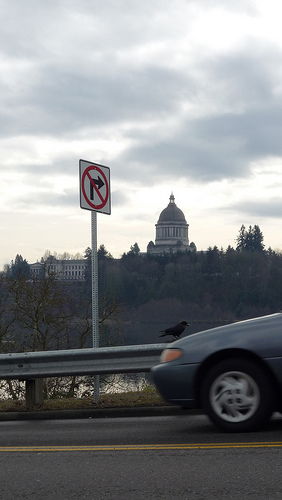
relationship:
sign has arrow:
[76, 158, 115, 218] [94, 175, 106, 186]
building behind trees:
[148, 190, 201, 252] [102, 247, 281, 300]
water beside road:
[44, 372, 150, 393] [7, 421, 277, 496]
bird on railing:
[158, 319, 190, 338] [4, 344, 161, 370]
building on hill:
[148, 190, 201, 252] [19, 288, 278, 324]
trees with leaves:
[102, 247, 281, 300] [207, 253, 230, 277]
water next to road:
[44, 372, 150, 393] [7, 421, 277, 496]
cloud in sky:
[210, 54, 266, 112] [6, 4, 281, 260]